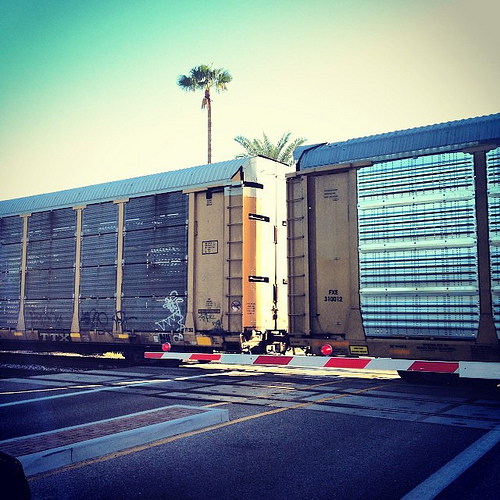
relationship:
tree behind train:
[165, 60, 255, 167] [0, 109, 495, 394]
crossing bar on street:
[142, 343, 499, 392] [5, 354, 492, 496]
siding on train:
[355, 147, 481, 341] [0, 109, 495, 394]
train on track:
[0, 109, 495, 394] [178, 370, 492, 429]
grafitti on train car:
[78, 288, 189, 335] [0, 155, 294, 352]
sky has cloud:
[14, 30, 421, 154] [275, 44, 493, 118]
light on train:
[319, 341, 331, 356] [0, 109, 495, 394]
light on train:
[159, 341, 173, 352] [0, 109, 495, 394]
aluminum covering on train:
[0, 113, 499, 214] [0, 109, 495, 394]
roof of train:
[0, 155, 254, 215] [0, 109, 495, 394]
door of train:
[193, 194, 225, 331] [0, 109, 495, 394]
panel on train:
[346, 173, 466, 323] [288, 139, 440, 335]